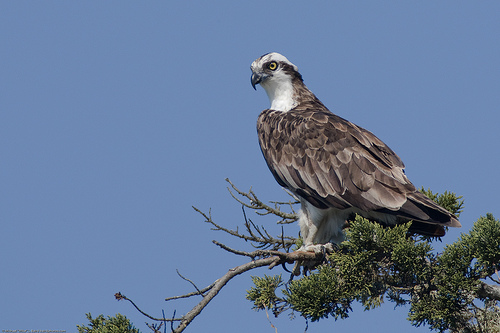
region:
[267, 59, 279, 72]
a glowing yellow eye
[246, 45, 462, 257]
a bird of prey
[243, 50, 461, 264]
a brown and white hawk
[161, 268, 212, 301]
a few bare branches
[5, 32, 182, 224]
a clear blue sky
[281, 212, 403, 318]
leaves covered in short leaves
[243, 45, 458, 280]
a hawk in a tree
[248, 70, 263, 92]
a hooked bird beak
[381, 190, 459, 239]
some long tail feathers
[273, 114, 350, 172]
a few brown feathers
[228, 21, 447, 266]
a bird of prey on a branch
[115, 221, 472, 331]
a thin evergreen branch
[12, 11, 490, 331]
a clear blue sky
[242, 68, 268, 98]
a bird of prey's hooked beak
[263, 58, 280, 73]
a bird of prey's left eye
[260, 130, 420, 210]
a bird of prey's left wing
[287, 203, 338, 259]
a bird of prey's left leg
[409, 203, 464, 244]
a bird of prey's tail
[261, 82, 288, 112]
a patch of white feathers on a bird of prey's throat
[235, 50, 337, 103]
a bird of prey's black and white head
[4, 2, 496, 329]
blue of daytime sky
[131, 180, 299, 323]
branches with no leaves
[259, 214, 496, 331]
green needles on branches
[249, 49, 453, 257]
bird standing on branch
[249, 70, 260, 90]
curved beak of bird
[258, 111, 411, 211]
leaves on bird wing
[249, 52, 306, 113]
white neck on head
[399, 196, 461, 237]
tail feathers on bird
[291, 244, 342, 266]
claws on tree branch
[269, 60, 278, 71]
round eye of bird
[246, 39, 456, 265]
the eagle on the branch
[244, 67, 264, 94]
the black beak of the bird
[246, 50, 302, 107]
the white head of the bird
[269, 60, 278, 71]
the yellow eye of the bird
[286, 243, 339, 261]
the claws on the branch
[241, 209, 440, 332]
the leaves on the branches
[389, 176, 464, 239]
the tail feathers of the bird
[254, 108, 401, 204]
the feathers on the wing of the bird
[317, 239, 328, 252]
the black claw on the birds foot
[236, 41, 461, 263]
the bird looking off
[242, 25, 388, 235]
large bird in tree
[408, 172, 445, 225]
bird has grey tail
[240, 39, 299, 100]
bird has white head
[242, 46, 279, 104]
bird has black beak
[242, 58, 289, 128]
bird has white neck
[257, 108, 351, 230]
bird has grey breast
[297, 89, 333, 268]
bird has white legs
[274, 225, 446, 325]
green leaves on branch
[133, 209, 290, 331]
branch is light grey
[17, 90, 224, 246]
blue and clear sky